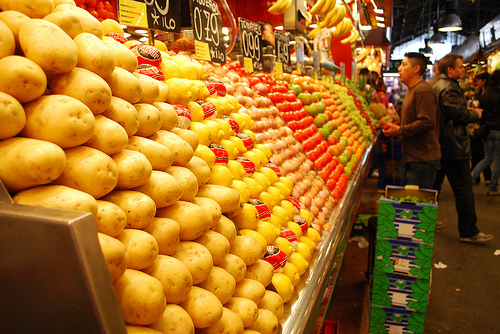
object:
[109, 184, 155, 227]
potato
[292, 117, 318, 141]
tomatoes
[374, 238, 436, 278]
boxes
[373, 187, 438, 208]
food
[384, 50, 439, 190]
man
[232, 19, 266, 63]
price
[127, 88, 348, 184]
food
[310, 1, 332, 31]
bananas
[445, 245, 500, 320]
ground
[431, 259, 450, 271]
trash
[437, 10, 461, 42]
lamp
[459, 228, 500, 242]
shoes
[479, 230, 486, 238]
shoelaces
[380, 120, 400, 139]
hand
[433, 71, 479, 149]
jacket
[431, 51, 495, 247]
man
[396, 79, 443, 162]
shirt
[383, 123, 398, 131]
pepper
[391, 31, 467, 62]
lights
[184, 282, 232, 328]
potatoes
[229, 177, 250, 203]
lemons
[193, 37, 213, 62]
signs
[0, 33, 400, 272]
vegetables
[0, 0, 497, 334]
store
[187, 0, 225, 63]
board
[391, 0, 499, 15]
ceiling